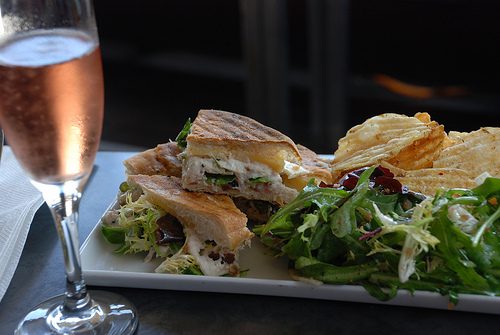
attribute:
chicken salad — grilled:
[177, 107, 304, 204]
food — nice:
[159, 110, 406, 254]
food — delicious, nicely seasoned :
[101, 108, 499, 294]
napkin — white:
[0, 146, 52, 300]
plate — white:
[79, 129, 496, 318]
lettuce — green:
[103, 203, 160, 250]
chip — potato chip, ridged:
[335, 112, 431, 172]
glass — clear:
[18, 39, 138, 315]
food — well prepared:
[119, 106, 496, 281]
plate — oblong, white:
[60, 152, 498, 313]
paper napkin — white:
[3, 191, 38, 306]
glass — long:
[2, 1, 138, 334]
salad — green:
[262, 163, 495, 278]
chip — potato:
[342, 122, 481, 173]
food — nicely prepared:
[158, 130, 436, 249]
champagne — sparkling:
[0, 26, 103, 182]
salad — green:
[252, 160, 499, 297]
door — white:
[98, 2, 495, 134]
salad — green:
[258, 167, 498, 292]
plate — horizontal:
[66, 166, 496, 313]